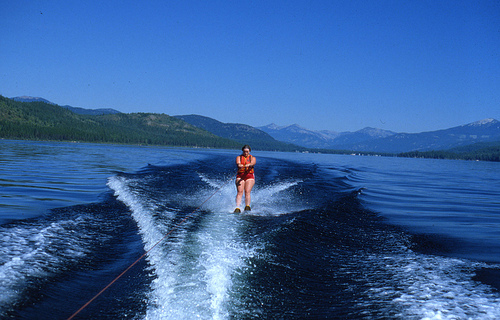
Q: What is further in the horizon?
A: Several blue mountains.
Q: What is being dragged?
A: The woman.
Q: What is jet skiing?
A: The woman.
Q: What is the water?
A: Calm.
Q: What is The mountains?
A: In the back.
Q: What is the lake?
A: Large.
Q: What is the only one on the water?
A: The woman.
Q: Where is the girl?
A: In the water.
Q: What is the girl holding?
A: A rope.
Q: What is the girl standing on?
A: Water skis.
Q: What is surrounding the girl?
A: Water.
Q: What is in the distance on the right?
A: Mountains.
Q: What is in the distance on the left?
A: Grassy hills.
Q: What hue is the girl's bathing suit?
A: Red.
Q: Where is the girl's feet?
A: On the water skis.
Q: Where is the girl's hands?
A: Holding the rope.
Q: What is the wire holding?
A: A woman.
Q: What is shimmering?
A: The watermark in the ocean.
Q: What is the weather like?
A: Clear.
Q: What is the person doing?
A: Water skiing.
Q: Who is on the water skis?
A: A person.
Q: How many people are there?
A: One.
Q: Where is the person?
A: On a lake.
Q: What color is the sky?
A: Blue.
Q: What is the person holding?
A: A tow rope.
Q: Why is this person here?
A: To ski.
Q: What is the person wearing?
A: A life jacket.